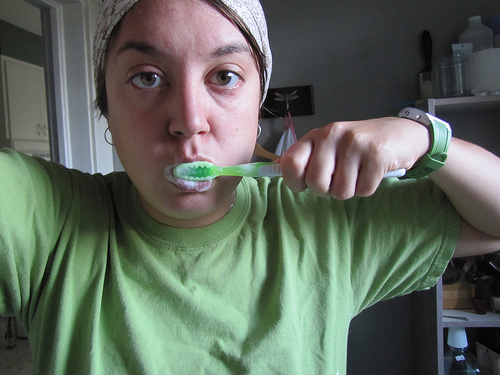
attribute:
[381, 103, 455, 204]
watch — green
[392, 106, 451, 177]
watch — green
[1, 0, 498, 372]
woman — brushing, wearing, holding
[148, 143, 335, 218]
toothbrush — green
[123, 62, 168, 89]
eye — brown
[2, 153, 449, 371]
shirt — green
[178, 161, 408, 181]
toothbrush — white, green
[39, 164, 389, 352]
shirt — green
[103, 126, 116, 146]
earring — hoop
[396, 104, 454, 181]
watch —   green and white,  woman's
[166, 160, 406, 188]
toothbrush — green, white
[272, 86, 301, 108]
dragonfly — gold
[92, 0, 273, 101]
hat — brown